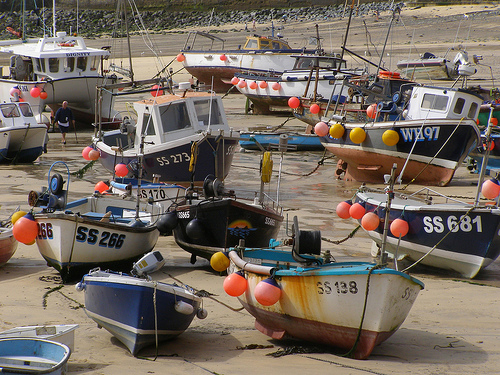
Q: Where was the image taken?
A: It was taken at the beach.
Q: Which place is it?
A: It is a beach.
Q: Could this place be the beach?
A: Yes, it is the beach.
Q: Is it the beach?
A: Yes, it is the beach.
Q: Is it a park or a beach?
A: It is a beach.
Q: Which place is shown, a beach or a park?
A: It is a beach.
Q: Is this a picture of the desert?
A: No, the picture is showing the beach.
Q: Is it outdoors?
A: Yes, it is outdoors.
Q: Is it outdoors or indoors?
A: It is outdoors.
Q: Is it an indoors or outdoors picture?
A: It is outdoors.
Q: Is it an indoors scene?
A: No, it is outdoors.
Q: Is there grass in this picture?
A: Yes, there is grass.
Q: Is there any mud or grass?
A: Yes, there is grass.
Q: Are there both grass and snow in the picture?
A: No, there is grass but no snow.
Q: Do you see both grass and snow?
A: No, there is grass but no snow.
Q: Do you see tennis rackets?
A: No, there are no tennis rackets.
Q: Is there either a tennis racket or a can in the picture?
A: No, there are no rackets or cans.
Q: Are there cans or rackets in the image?
A: No, there are no rackets or cans.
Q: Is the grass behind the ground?
A: Yes, the grass is behind the ground.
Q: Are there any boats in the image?
A: Yes, there is a boat.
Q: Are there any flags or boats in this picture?
A: Yes, there is a boat.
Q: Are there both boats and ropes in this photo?
A: Yes, there are both a boat and a rope.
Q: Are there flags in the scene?
A: No, there are no flags.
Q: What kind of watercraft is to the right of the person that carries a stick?
A: The watercraft is a boat.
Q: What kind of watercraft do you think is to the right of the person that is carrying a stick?
A: The watercraft is a boat.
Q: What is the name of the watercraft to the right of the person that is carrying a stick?
A: The watercraft is a boat.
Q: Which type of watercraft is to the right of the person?
A: The watercraft is a boat.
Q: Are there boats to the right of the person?
A: Yes, there is a boat to the right of the person.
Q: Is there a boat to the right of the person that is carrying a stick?
A: Yes, there is a boat to the right of the person.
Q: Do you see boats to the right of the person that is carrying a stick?
A: Yes, there is a boat to the right of the person.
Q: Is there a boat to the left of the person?
A: No, the boat is to the right of the person.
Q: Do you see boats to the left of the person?
A: No, the boat is to the right of the person.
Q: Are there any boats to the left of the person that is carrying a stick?
A: No, the boat is to the right of the person.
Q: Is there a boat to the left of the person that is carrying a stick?
A: No, the boat is to the right of the person.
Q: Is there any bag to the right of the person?
A: No, there is a boat to the right of the person.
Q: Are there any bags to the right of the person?
A: No, there is a boat to the right of the person.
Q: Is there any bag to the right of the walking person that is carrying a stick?
A: No, there is a boat to the right of the person.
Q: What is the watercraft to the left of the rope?
A: The watercraft is a boat.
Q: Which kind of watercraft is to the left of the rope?
A: The watercraft is a boat.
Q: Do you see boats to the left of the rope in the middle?
A: Yes, there is a boat to the left of the rope.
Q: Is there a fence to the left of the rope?
A: No, there is a boat to the left of the rope.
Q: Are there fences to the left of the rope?
A: No, there is a boat to the left of the rope.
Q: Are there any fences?
A: No, there are no fences.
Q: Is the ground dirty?
A: Yes, the ground is dirty.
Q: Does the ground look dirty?
A: Yes, the ground is dirty.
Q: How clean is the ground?
A: The ground is dirty.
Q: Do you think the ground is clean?
A: No, the ground is dirty.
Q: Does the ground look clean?
A: No, the ground is dirty.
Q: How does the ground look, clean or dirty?
A: The ground is dirty.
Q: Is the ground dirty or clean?
A: The ground is dirty.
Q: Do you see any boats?
A: Yes, there is a boat.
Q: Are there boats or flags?
A: Yes, there is a boat.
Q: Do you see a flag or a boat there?
A: Yes, there is a boat.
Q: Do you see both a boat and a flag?
A: No, there is a boat but no flags.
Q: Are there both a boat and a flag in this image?
A: No, there is a boat but no flags.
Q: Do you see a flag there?
A: No, there are no flags.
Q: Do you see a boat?
A: Yes, there is a boat.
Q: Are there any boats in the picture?
A: Yes, there is a boat.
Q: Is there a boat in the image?
A: Yes, there is a boat.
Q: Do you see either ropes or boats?
A: Yes, there is a boat.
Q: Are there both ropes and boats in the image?
A: Yes, there are both a boat and a rope.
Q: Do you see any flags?
A: No, there are no flags.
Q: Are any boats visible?
A: Yes, there is a boat.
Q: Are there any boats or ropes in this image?
A: Yes, there is a boat.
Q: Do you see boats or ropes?
A: Yes, there is a boat.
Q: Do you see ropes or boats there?
A: Yes, there is a boat.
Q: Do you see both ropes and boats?
A: Yes, there are both a boat and a rope.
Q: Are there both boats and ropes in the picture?
A: Yes, there are both a boat and a rope.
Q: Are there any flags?
A: No, there are no flags.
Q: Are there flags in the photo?
A: No, there are no flags.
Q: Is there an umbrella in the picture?
A: No, there are no umbrellas.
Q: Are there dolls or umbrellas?
A: No, there are no umbrellas or dolls.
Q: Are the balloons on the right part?
A: Yes, the balloons are on the right of the image.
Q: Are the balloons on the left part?
A: No, the balloons are on the right of the image.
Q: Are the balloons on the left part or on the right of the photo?
A: The balloons are on the right of the image.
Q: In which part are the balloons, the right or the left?
A: The balloons are on the right of the image.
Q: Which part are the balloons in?
A: The balloons are on the right of the image.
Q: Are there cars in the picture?
A: No, there are no cars.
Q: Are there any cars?
A: No, there are no cars.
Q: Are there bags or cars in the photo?
A: No, there are no cars or bags.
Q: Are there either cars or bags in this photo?
A: No, there are no cars or bags.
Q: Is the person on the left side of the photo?
A: Yes, the person is on the left of the image.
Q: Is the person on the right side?
A: No, the person is on the left of the image.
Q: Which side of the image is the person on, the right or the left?
A: The person is on the left of the image.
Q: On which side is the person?
A: The person is on the left of the image.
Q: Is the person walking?
A: Yes, the person is walking.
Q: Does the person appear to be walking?
A: Yes, the person is walking.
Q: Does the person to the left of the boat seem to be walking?
A: Yes, the person is walking.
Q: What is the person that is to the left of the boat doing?
A: The person is walking.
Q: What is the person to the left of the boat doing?
A: The person is walking.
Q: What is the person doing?
A: The person is walking.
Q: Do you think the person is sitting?
A: No, the person is walking.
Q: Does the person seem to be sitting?
A: No, the person is walking.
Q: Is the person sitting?
A: No, the person is walking.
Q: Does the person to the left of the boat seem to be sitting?
A: No, the person is walking.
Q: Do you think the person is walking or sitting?
A: The person is walking.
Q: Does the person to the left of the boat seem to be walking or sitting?
A: The person is walking.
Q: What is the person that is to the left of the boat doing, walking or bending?
A: The person is walking.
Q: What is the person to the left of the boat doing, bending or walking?
A: The person is walking.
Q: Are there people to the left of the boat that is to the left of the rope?
A: Yes, there is a person to the left of the boat.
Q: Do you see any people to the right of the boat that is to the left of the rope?
A: No, the person is to the left of the boat.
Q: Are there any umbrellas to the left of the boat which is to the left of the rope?
A: No, there is a person to the left of the boat.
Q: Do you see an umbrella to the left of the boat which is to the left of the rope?
A: No, there is a person to the left of the boat.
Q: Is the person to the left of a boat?
A: Yes, the person is to the left of a boat.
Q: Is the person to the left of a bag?
A: No, the person is to the left of a boat.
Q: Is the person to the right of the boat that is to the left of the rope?
A: No, the person is to the left of the boat.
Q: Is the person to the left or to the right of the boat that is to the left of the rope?
A: The person is to the left of the boat.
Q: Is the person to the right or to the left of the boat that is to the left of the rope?
A: The person is to the left of the boat.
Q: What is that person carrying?
A: The person is carrying a stick.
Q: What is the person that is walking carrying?
A: The person is carrying a stick.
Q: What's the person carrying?
A: The person is carrying a stick.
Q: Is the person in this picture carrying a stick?
A: Yes, the person is carrying a stick.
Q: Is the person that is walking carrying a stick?
A: Yes, the person is carrying a stick.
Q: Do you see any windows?
A: Yes, there is a window.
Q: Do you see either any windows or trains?
A: Yes, there is a window.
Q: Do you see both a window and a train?
A: No, there is a window but no trains.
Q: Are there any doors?
A: No, there are no doors.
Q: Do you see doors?
A: No, there are no doors.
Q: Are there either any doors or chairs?
A: No, there are no doors or chairs.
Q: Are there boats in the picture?
A: Yes, there is a boat.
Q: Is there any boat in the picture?
A: Yes, there is a boat.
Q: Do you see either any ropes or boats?
A: Yes, there is a boat.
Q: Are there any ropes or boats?
A: Yes, there is a boat.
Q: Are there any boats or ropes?
A: Yes, there is a boat.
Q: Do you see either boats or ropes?
A: Yes, there is a boat.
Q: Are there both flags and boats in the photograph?
A: No, there is a boat but no flags.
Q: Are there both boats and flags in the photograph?
A: No, there is a boat but no flags.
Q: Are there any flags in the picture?
A: No, there are no flags.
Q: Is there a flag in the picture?
A: No, there are no flags.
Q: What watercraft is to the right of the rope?
A: The watercraft is a boat.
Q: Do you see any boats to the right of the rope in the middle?
A: Yes, there is a boat to the right of the rope.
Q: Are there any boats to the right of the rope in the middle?
A: Yes, there is a boat to the right of the rope.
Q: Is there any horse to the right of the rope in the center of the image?
A: No, there is a boat to the right of the rope.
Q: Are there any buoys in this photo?
A: Yes, there is a buoy.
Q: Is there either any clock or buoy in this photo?
A: Yes, there is a buoy.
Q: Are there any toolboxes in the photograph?
A: No, there are no toolboxes.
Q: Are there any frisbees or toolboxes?
A: No, there are no toolboxes or frisbees.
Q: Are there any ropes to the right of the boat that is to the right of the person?
A: Yes, there is a rope to the right of the boat.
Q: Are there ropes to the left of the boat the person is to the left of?
A: No, the rope is to the right of the boat.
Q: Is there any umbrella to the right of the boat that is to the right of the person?
A: No, there is a rope to the right of the boat.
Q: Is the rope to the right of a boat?
A: Yes, the rope is to the right of a boat.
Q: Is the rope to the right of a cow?
A: No, the rope is to the right of a boat.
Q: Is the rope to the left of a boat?
A: No, the rope is to the right of a boat.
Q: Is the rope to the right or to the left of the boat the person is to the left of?
A: The rope is to the right of the boat.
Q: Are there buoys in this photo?
A: Yes, there is a buoy.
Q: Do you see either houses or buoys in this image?
A: Yes, there is a buoy.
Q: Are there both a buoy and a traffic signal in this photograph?
A: No, there is a buoy but no traffic lights.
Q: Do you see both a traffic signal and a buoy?
A: No, there is a buoy but no traffic lights.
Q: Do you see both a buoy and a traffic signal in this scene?
A: No, there is a buoy but no traffic lights.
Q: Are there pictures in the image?
A: No, there are no pictures.